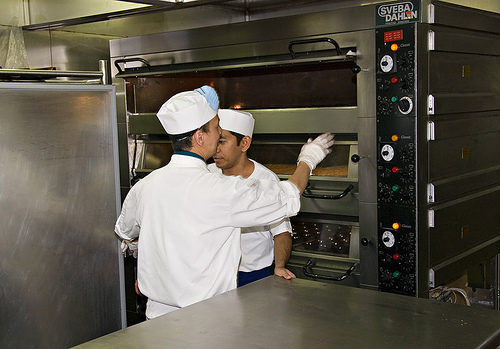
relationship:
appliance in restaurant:
[110, 9, 498, 300] [0, 3, 499, 343]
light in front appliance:
[223, 76, 273, 119] [59, 17, 389, 131]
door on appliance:
[1, 81, 127, 346] [0, 8, 494, 344]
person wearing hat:
[199, 105, 296, 286] [214, 106, 258, 138]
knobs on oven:
[377, 23, 417, 295] [106, 1, 499, 293]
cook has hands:
[131, 92, 227, 320] [295, 135, 335, 180]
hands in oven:
[295, 135, 335, 180] [325, 5, 395, 277]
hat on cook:
[123, 65, 245, 150] [112, 85, 334, 319]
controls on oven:
[371, 25, 427, 299] [106, 1, 499, 293]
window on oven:
[115, 64, 355, 114] [106, 1, 499, 293]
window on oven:
[130, 132, 365, 189] [106, 1, 499, 293]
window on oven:
[288, 211, 365, 256] [106, 1, 499, 293]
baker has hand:
[114, 85, 335, 318] [294, 129, 338, 174]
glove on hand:
[295, 126, 337, 174] [294, 129, 338, 174]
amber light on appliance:
[387, 213, 404, 235] [101, 2, 496, 324]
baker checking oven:
[114, 86, 337, 318] [263, 127, 438, 198]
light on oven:
[389, 42, 397, 52] [106, 1, 499, 293]